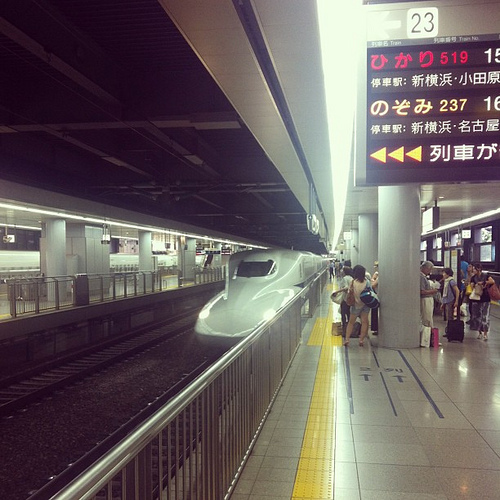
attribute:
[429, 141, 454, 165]
letter — white, asian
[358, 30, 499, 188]
sign — black, hiragana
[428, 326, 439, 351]
bag — red, pink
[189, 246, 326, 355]
train — parked, white, approaching, high speed, moving, pulling into station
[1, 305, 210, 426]
tracks — on ground, black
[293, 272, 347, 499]
line — yellow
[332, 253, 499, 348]
people — waiting, bunched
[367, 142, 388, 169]
arrow — yellow, pointing left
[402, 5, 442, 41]
number — white, black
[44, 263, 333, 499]
railing — metal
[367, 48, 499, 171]
writing — japanese